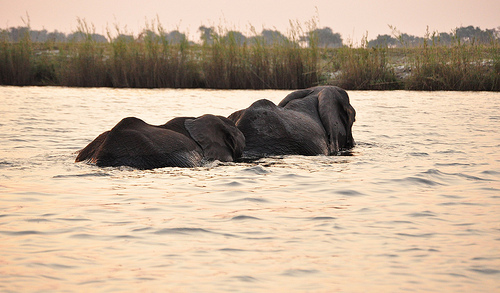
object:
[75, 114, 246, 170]
elephant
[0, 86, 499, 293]
water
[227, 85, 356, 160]
elephant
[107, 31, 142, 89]
plant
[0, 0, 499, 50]
sky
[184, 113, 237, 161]
ear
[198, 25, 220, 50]
tree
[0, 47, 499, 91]
field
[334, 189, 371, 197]
wave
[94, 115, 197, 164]
spine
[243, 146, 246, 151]
eye